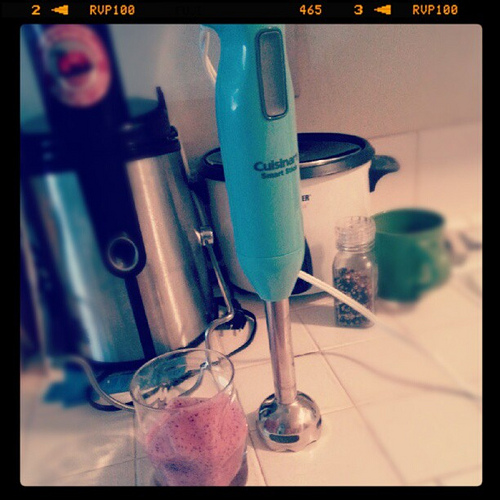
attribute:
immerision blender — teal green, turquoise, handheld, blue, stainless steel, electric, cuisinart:
[196, 24, 326, 455]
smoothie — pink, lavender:
[132, 348, 253, 488]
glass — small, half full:
[131, 345, 253, 488]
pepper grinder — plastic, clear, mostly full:
[330, 209, 382, 331]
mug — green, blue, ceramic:
[372, 207, 455, 304]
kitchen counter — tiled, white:
[21, 214, 483, 488]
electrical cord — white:
[299, 268, 482, 408]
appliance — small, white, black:
[198, 131, 400, 298]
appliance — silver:
[18, 85, 237, 376]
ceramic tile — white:
[320, 342, 472, 413]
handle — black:
[368, 153, 401, 193]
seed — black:
[189, 417, 197, 425]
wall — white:
[21, 25, 482, 220]